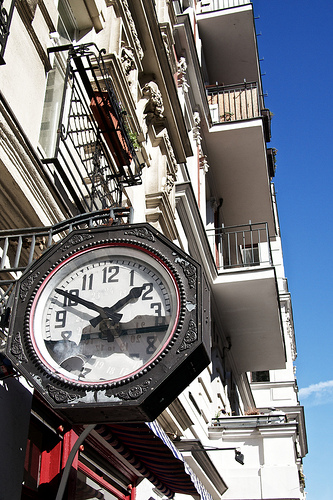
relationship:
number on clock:
[51, 332, 73, 353] [5, 223, 211, 418]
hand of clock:
[49, 286, 122, 324] [5, 223, 211, 418]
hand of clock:
[92, 285, 143, 327] [5, 223, 211, 418]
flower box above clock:
[86, 83, 134, 173] [5, 223, 211, 418]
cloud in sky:
[301, 384, 333, 399] [296, 6, 332, 498]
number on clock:
[103, 264, 117, 283] [5, 223, 211, 418]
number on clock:
[127, 267, 139, 285] [5, 223, 211, 418]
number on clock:
[149, 303, 161, 318] [5, 223, 211, 418]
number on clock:
[52, 308, 69, 329] [5, 223, 211, 418]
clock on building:
[5, 223, 211, 418] [4, 5, 309, 498]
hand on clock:
[49, 286, 122, 324] [5, 223, 211, 418]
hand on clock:
[92, 285, 143, 327] [5, 223, 211, 418]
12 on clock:
[103, 264, 117, 283] [5, 223, 211, 418]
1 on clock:
[127, 267, 139, 285] [5, 223, 211, 418]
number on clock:
[141, 282, 155, 301] [5, 223, 211, 418]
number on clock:
[81, 275, 93, 291] [5, 223, 211, 418]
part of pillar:
[260, 433, 300, 499] [257, 382, 293, 499]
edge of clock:
[183, 258, 210, 362] [5, 223, 211, 418]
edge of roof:
[194, 8, 258, 21] [196, 9, 260, 88]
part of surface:
[226, 134, 266, 187] [223, 136, 272, 233]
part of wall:
[282, 423, 303, 457] [211, 419, 301, 499]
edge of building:
[258, 121, 283, 240] [4, 5, 309, 498]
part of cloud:
[302, 384, 324, 402] [301, 384, 333, 399]